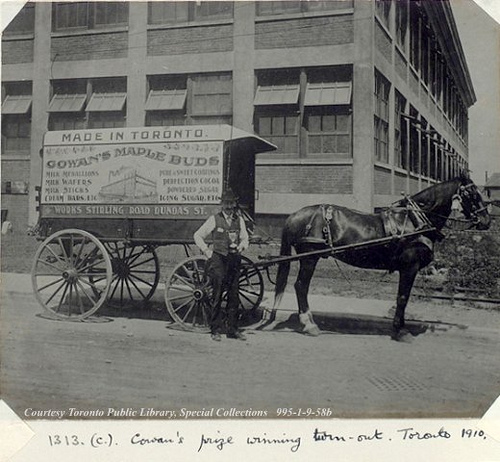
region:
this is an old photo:
[74, 55, 399, 369]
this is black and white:
[110, 93, 311, 303]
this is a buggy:
[44, 84, 335, 362]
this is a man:
[174, 175, 255, 317]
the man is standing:
[204, 191, 311, 346]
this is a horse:
[278, 171, 453, 379]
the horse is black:
[312, 188, 472, 380]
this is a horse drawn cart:
[33, 102, 496, 322]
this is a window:
[0, 94, 33, 139]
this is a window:
[42, 88, 94, 125]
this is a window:
[85, 83, 137, 128]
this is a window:
[146, 88, 188, 129]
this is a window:
[252, 93, 304, 136]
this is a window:
[306, 91, 358, 134]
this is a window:
[365, 115, 396, 156]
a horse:
[276, 182, 485, 329]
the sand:
[278, 341, 360, 406]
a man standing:
[196, 199, 255, 313]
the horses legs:
[396, 264, 417, 334]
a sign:
[44, 131, 224, 225]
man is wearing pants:
[213, 260, 242, 318]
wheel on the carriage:
[36, 232, 115, 321]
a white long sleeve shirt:
[201, 226, 214, 234]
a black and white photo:
[2, 7, 497, 405]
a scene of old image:
[5, 6, 497, 431]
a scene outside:
[1, 0, 498, 442]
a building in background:
[1, 3, 471, 286]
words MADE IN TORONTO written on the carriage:
[46, 119, 213, 146]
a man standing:
[182, 177, 267, 350]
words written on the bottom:
[22, 393, 499, 460]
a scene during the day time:
[4, 3, 499, 460]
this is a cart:
[32, 108, 259, 276]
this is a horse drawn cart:
[16, 108, 496, 352]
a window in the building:
[255, 92, 308, 146]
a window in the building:
[136, 95, 191, 137]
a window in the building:
[91, 80, 130, 136]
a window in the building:
[46, 77, 88, 134]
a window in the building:
[2, 75, 39, 135]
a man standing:
[191, 204, 271, 342]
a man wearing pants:
[206, 246, 246, 341]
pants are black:
[205, 255, 241, 331]